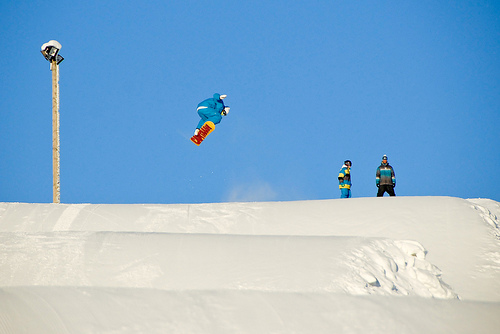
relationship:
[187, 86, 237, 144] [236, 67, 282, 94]
person in air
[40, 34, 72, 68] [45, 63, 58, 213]
light on pole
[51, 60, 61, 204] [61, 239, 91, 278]
pole in snow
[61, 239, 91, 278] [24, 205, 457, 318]
snow on hill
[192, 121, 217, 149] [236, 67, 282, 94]
snowboard in air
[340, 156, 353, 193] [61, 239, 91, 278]
man in snow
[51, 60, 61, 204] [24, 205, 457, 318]
pole on hill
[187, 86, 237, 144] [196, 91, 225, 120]
person wearing jacket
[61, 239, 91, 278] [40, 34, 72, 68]
snow on light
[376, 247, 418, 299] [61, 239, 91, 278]
track in snow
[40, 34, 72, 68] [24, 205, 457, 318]
light on hill